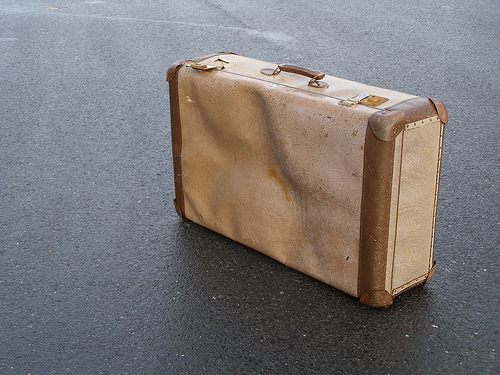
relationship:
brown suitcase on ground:
[162, 51, 450, 308] [1, 1, 498, 374]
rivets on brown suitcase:
[386, 105, 447, 310] [162, 51, 450, 308]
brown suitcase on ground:
[162, 51, 450, 308] [62, 314, 492, 374]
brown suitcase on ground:
[155, 57, 450, 296] [1, 1, 498, 374]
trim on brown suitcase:
[353, 95, 448, 307] [162, 51, 450, 308]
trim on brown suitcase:
[166, 49, 236, 220] [162, 51, 450, 308]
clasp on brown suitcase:
[338, 89, 372, 110] [162, 51, 450, 308]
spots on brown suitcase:
[350, 128, 360, 138] [162, 51, 450, 308]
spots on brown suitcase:
[358, 145, 364, 153] [162, 51, 450, 308]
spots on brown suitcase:
[321, 132, 331, 141] [162, 51, 450, 308]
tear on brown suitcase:
[188, 60, 224, 75] [162, 51, 450, 308]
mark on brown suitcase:
[180, 88, 198, 111] [162, 51, 450, 308]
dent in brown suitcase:
[200, 86, 310, 237] [162, 51, 450, 308]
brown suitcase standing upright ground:
[162, 51, 450, 308] [0, 1, 500, 375]